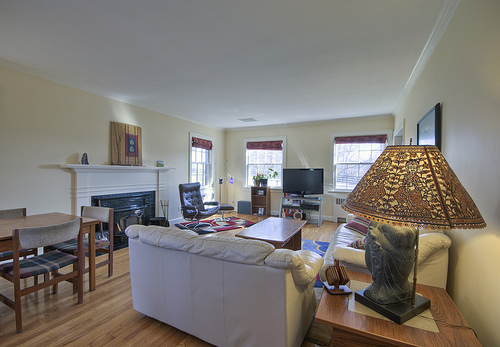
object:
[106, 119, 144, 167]
picture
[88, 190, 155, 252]
fireplace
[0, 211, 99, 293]
table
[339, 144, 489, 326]
lamp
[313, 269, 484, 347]
table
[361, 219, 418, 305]
figurine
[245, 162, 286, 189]
window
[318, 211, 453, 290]
couch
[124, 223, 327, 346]
couch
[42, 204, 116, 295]
chairs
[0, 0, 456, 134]
ceiling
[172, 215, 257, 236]
carpet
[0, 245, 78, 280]
plaid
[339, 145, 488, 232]
shade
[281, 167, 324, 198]
television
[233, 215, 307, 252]
table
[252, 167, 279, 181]
plants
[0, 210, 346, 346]
floor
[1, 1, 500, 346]
house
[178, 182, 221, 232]
chair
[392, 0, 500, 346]
wall